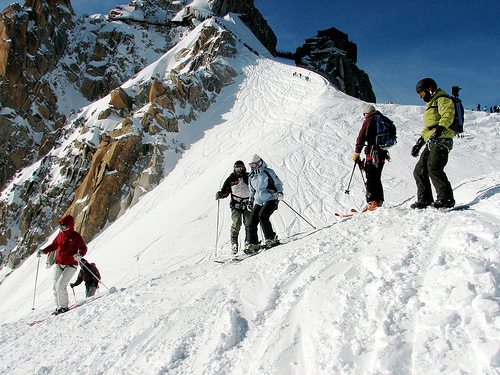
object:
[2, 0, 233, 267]
rocks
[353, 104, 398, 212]
person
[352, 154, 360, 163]
hand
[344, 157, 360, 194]
pole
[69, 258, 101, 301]
skier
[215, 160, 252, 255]
man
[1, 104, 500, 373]
hillside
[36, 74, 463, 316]
group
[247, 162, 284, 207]
jacket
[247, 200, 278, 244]
pants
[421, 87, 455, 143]
green jacket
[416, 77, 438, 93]
helmet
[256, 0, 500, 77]
sky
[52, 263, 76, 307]
trousers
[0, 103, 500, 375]
ground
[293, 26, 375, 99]
rocky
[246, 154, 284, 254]
person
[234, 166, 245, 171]
goggles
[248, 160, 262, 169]
goggles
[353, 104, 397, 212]
man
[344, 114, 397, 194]
outfit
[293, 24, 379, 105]
rock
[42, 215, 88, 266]
jacket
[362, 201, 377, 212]
ski boots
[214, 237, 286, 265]
ski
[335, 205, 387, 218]
ski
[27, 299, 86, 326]
ski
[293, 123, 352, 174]
track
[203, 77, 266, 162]
track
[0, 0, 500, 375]
snow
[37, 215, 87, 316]
people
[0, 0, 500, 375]
hill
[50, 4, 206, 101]
snow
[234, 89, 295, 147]
snow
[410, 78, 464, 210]
man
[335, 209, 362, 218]
skis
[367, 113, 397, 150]
backpack